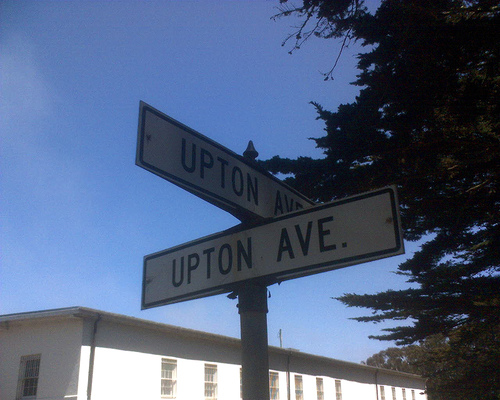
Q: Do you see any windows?
A: Yes, there is a window.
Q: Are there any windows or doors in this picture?
A: Yes, there is a window.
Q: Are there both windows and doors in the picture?
A: No, there is a window but no doors.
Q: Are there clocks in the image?
A: No, there are no clocks.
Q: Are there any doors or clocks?
A: No, there are no clocks or doors.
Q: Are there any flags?
A: No, there are no flags.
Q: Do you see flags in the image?
A: No, there are no flags.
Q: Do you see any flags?
A: No, there are no flags.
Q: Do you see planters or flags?
A: No, there are no flags or planters.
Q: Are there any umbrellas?
A: No, there are no umbrellas.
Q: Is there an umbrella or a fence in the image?
A: No, there are no umbrellas or fences.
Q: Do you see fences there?
A: No, there are no fences.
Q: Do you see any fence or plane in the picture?
A: No, there are no fences or airplanes.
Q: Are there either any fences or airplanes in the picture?
A: No, there are no fences or airplanes.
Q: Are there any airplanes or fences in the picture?
A: No, there are no fences or airplanes.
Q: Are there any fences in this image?
A: No, there are no fences.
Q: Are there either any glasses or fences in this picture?
A: No, there are no fences or glasses.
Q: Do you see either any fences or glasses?
A: No, there are no fences or glasses.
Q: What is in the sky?
A: The clouds are in the sky.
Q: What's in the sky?
A: The clouds are in the sky.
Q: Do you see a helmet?
A: No, there are no helmets.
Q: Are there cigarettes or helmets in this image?
A: No, there are no helmets or cigarettes.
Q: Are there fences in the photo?
A: No, there are no fences.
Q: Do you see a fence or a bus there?
A: No, there are no fences or buses.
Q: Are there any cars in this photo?
A: No, there are no cars.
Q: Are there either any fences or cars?
A: No, there are no cars or fences.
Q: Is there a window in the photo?
A: Yes, there is a window.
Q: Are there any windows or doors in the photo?
A: Yes, there is a window.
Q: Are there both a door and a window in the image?
A: No, there is a window but no doors.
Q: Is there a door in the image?
A: No, there are no doors.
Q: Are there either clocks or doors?
A: No, there are no doors or clocks.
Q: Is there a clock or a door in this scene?
A: No, there are no doors or clocks.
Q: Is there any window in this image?
A: Yes, there is a window.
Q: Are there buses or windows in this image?
A: Yes, there is a window.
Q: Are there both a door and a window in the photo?
A: No, there is a window but no doors.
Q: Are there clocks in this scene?
A: No, there are no clocks.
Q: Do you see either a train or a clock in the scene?
A: No, there are no clocks or trains.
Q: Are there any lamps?
A: No, there are no lamps.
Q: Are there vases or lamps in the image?
A: No, there are no lamps or vases.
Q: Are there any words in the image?
A: Yes, there are words.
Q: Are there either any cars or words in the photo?
A: Yes, there are words.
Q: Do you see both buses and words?
A: No, there are words but no buses.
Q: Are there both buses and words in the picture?
A: No, there are words but no buses.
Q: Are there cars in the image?
A: No, there are no cars.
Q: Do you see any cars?
A: No, there are no cars.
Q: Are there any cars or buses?
A: No, there are no cars or buses.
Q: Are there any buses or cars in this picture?
A: No, there are no cars or buses.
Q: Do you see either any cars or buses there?
A: No, there are no cars or buses.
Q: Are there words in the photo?
A: Yes, there are words.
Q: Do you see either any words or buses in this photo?
A: Yes, there are words.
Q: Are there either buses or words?
A: Yes, there are words.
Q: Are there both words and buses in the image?
A: No, there are words but no buses.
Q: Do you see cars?
A: No, there are no cars.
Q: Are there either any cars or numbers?
A: No, there are no cars or numbers.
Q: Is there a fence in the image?
A: No, there are no fences.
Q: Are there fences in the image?
A: No, there are no fences.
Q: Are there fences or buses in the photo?
A: No, there are no fences or buses.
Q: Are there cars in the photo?
A: No, there are no cars.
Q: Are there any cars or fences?
A: No, there are no cars or fences.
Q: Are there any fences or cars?
A: No, there are no cars or fences.